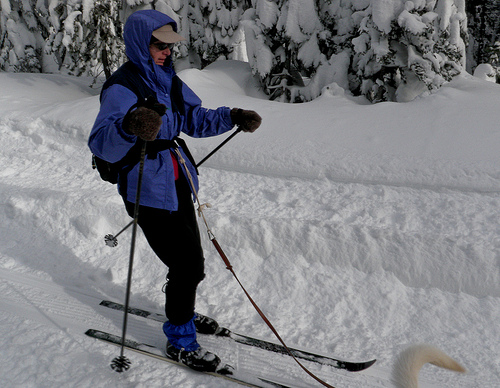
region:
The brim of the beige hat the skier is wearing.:
[150, 27, 185, 44]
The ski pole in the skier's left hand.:
[120, 143, 150, 368]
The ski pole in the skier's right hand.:
[85, 130, 251, 242]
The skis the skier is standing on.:
[87, 315, 347, 385]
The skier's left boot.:
[164, 324, 223, 372]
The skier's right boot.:
[182, 297, 219, 334]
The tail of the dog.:
[390, 343, 468, 386]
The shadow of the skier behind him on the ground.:
[0, 161, 164, 341]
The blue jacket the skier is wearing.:
[82, 7, 240, 202]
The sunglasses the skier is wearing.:
[150, 35, 176, 53]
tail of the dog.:
[397, 340, 453, 380]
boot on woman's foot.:
[183, 343, 218, 369]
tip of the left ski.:
[344, 351, 379, 381]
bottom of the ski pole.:
[110, 348, 130, 378]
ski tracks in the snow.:
[36, 288, 77, 315]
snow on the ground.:
[392, 118, 454, 153]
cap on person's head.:
[153, 28, 177, 43]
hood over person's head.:
[125, 13, 153, 53]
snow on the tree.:
[371, 12, 413, 29]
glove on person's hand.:
[230, 108, 260, 135]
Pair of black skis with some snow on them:
[84, 294, 380, 386]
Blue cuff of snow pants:
[160, 313, 205, 355]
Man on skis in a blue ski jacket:
[86, 6, 263, 375]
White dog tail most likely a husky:
[389, 342, 464, 387]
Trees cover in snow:
[192, 0, 486, 87]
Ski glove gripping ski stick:
[130, 100, 166, 145]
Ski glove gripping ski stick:
[226, 103, 264, 138]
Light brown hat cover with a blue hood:
[120, 8, 185, 46]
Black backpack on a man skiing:
[87, 63, 147, 189]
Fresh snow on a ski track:
[272, 163, 488, 312]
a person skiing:
[51, 8, 387, 385]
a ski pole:
[108, 132, 146, 379]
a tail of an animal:
[382, 333, 467, 380]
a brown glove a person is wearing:
[123, 103, 163, 145]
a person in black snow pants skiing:
[84, 2, 247, 379]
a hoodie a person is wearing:
[119, 7, 165, 77]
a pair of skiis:
[81, 294, 379, 382]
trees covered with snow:
[207, 6, 466, 76]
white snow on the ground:
[300, 169, 429, 271]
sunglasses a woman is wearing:
[149, 42, 176, 52]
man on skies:
[85, 5, 277, 370]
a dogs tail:
[374, 344, 468, 384]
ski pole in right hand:
[107, 100, 159, 372]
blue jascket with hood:
[89, 11, 236, 212]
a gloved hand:
[121, 108, 165, 150]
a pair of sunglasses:
[152, 36, 182, 56]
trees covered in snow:
[254, 4, 483, 108]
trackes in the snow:
[306, 129, 497, 280]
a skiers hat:
[142, 19, 194, 49]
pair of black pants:
[123, 171, 223, 331]